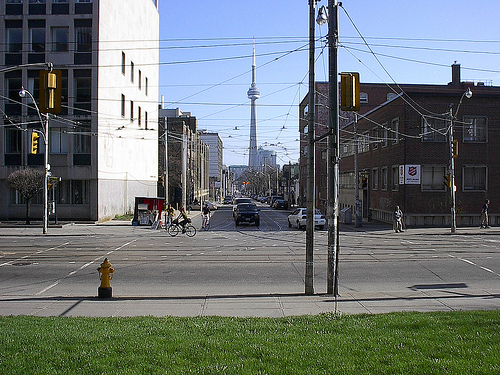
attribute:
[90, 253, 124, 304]
fire hydrant — yellow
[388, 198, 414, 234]
person — standing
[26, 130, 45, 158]
cover — yellow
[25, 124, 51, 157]
traffic light — hanging, yellow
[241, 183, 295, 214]
cars — parked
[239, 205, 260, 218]
people — sitting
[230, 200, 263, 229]
vehicle — stopped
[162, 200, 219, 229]
people — walking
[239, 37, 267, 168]
building — tall, white, large, pointed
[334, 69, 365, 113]
street light — hanging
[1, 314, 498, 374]
grass — bright, green, lush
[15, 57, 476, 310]
intersection — large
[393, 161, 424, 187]
sign — red, white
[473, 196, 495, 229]
man — walking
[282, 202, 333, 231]
car — white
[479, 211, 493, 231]
pants — tan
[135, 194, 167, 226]
newstand — red